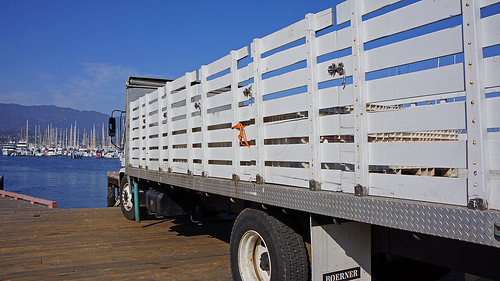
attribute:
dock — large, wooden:
[128, 0, 498, 208]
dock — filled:
[3, 137, 116, 222]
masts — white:
[3, 108, 123, 159]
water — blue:
[4, 143, 124, 213]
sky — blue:
[1, 1, 498, 120]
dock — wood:
[1, 178, 231, 279]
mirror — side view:
[106, 110, 122, 144]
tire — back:
[227, 204, 313, 279]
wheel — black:
[224, 206, 317, 277]